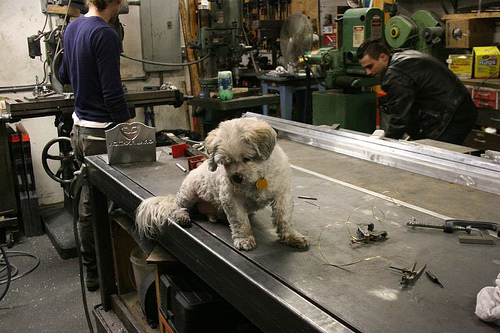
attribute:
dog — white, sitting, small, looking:
[134, 117, 312, 250]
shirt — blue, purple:
[58, 16, 132, 124]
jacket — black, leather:
[380, 49, 470, 140]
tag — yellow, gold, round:
[256, 177, 269, 191]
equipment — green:
[305, 7, 446, 133]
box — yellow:
[473, 46, 500, 80]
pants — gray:
[70, 123, 112, 285]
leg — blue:
[277, 84, 293, 120]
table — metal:
[81, 126, 500, 332]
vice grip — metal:
[407, 218, 499, 244]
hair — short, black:
[356, 39, 391, 59]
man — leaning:
[354, 40, 480, 144]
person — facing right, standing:
[59, 0, 131, 291]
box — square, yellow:
[446, 53, 472, 79]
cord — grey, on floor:
[1, 249, 40, 284]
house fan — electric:
[278, 12, 314, 123]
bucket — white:
[129, 247, 157, 313]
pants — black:
[439, 97, 478, 145]